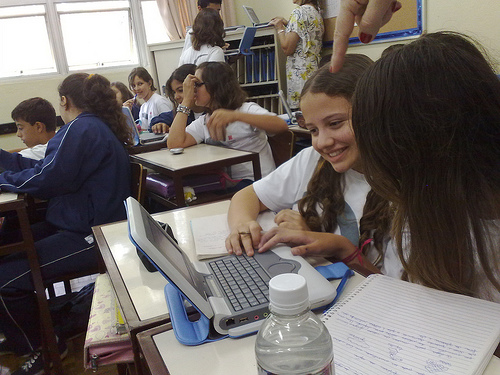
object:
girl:
[223, 53, 401, 280]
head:
[299, 53, 373, 173]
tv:
[122, 197, 337, 336]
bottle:
[255, 272, 335, 374]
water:
[254, 320, 333, 374]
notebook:
[317, 272, 499, 374]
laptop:
[123, 195, 337, 338]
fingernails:
[358, 33, 371, 43]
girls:
[350, 30, 499, 308]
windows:
[54, 10, 141, 69]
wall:
[1, 0, 499, 154]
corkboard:
[311, 0, 424, 44]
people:
[186, 7, 229, 70]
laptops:
[243, 3, 272, 31]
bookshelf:
[226, 27, 286, 119]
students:
[0, 73, 134, 374]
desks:
[136, 288, 499, 375]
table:
[91, 196, 341, 369]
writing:
[336, 308, 474, 359]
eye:
[326, 118, 343, 130]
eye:
[307, 125, 317, 136]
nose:
[314, 128, 334, 151]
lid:
[268, 272, 308, 306]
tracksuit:
[0, 115, 131, 356]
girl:
[0, 69, 142, 374]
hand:
[327, 0, 403, 75]